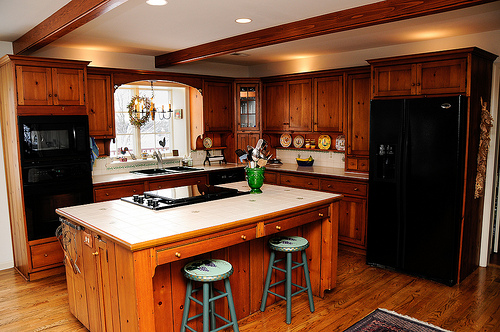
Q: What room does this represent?
A: It represents the kitchen.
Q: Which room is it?
A: It is a kitchen.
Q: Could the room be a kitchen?
A: Yes, it is a kitchen.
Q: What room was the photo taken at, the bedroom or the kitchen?
A: It was taken at the kitchen.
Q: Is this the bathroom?
A: No, it is the kitchen.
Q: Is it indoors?
A: Yes, it is indoors.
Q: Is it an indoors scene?
A: Yes, it is indoors.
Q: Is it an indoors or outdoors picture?
A: It is indoors.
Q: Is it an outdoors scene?
A: No, it is indoors.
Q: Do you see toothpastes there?
A: No, there are no toothpastes.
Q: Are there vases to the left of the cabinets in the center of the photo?
A: Yes, there is a vase to the left of the cabinets.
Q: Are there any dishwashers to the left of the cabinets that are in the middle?
A: No, there is a vase to the left of the cabinets.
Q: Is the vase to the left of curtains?
A: No, the vase is to the left of the cabinets.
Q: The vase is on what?
A: The vase is on the counter.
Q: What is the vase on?
A: The vase is on the counter.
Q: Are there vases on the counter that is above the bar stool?
A: Yes, there is a vase on the counter.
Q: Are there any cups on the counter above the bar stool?
A: No, there is a vase on the counter.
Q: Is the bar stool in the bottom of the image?
A: Yes, the bar stool is in the bottom of the image.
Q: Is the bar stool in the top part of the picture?
A: No, the bar stool is in the bottom of the image.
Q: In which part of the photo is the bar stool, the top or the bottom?
A: The bar stool is in the bottom of the image.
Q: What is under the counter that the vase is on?
A: The bar stool is under the counter.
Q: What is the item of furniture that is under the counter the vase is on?
A: The piece of furniture is a bar stool.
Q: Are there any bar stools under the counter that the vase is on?
A: Yes, there is a bar stool under the counter.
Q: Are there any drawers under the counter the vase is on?
A: No, there is a bar stool under the counter.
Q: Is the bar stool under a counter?
A: Yes, the bar stool is under a counter.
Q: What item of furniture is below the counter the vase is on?
A: The piece of furniture is a bar stool.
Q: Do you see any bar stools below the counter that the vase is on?
A: Yes, there is a bar stool below the counter.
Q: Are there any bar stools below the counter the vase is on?
A: Yes, there is a bar stool below the counter.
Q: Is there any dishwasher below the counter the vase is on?
A: No, there is a bar stool below the counter.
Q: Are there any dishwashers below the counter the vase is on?
A: No, there is a bar stool below the counter.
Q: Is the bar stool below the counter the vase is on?
A: Yes, the bar stool is below the counter.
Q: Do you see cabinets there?
A: Yes, there is a cabinet.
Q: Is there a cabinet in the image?
A: Yes, there is a cabinet.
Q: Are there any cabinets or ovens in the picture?
A: Yes, there is a cabinet.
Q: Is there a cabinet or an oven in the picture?
A: Yes, there is a cabinet.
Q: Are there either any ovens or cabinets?
A: Yes, there is a cabinet.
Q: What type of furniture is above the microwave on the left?
A: The piece of furniture is a cabinet.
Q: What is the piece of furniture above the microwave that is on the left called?
A: The piece of furniture is a cabinet.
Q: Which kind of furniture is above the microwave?
A: The piece of furniture is a cabinet.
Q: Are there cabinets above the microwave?
A: Yes, there is a cabinet above the microwave.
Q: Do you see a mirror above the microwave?
A: No, there is a cabinet above the microwave.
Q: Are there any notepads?
A: No, there are no notepads.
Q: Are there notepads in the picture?
A: No, there are no notepads.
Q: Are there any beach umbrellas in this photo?
A: No, there are no beach umbrellas.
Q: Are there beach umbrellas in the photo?
A: No, there are no beach umbrellas.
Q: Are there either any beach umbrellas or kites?
A: No, there are no beach umbrellas or kites.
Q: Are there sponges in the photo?
A: No, there are no sponges.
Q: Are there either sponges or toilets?
A: No, there are no sponges or toilets.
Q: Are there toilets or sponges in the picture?
A: No, there are no sponges or toilets.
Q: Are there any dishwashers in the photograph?
A: No, there are no dishwashers.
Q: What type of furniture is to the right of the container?
A: The pieces of furniture are cabinets.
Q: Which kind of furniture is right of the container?
A: The pieces of furniture are cabinets.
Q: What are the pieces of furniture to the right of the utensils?
A: The pieces of furniture are cabinets.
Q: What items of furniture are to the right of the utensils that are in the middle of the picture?
A: The pieces of furniture are cabinets.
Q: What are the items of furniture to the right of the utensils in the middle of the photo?
A: The pieces of furniture are cabinets.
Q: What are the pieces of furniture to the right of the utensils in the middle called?
A: The pieces of furniture are cabinets.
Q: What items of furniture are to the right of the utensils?
A: The pieces of furniture are cabinets.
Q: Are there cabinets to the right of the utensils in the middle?
A: Yes, there are cabinets to the right of the utensils.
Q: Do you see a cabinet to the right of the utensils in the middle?
A: Yes, there are cabinets to the right of the utensils.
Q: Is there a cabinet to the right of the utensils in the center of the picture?
A: Yes, there are cabinets to the right of the utensils.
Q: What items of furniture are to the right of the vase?
A: The pieces of furniture are cabinets.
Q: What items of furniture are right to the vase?
A: The pieces of furniture are cabinets.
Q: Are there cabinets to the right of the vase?
A: Yes, there are cabinets to the right of the vase.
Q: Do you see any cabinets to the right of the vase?
A: Yes, there are cabinets to the right of the vase.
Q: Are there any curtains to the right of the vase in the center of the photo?
A: No, there are cabinets to the right of the vase.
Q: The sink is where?
A: The sink is in the kitchen.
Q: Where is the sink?
A: The sink is in the kitchen.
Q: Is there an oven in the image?
A: Yes, there is an oven.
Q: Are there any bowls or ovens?
A: Yes, there is an oven.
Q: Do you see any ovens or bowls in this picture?
A: Yes, there is an oven.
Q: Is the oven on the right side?
A: No, the oven is on the left of the image.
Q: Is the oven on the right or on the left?
A: The oven is on the left of the image.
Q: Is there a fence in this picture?
A: No, there are no fences.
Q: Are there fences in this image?
A: No, there are no fences.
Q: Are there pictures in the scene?
A: No, there are no pictures.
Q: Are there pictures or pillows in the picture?
A: No, there are no pictures or pillows.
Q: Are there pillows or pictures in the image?
A: No, there are no pictures or pillows.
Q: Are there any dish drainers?
A: No, there are no dish drainers.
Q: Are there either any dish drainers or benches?
A: No, there are no dish drainers or benches.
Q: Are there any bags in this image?
A: No, there are no bags.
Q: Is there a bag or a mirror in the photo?
A: No, there are no bags or mirrors.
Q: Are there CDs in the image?
A: No, there are no cds.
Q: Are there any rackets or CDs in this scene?
A: No, there are no CDs or rackets.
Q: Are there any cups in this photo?
A: No, there are no cups.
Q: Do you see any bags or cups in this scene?
A: No, there are no cups or bags.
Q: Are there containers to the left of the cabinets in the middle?
A: Yes, there is a container to the left of the cabinets.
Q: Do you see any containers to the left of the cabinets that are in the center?
A: Yes, there is a container to the left of the cabinets.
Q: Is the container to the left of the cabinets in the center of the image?
A: Yes, the container is to the left of the cabinets.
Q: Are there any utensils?
A: Yes, there are utensils.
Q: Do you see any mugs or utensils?
A: Yes, there are utensils.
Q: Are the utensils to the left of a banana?
A: Yes, the utensils are to the left of a banana.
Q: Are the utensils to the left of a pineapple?
A: No, the utensils are to the left of a banana.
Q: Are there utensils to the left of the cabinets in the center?
A: Yes, there are utensils to the left of the cabinets.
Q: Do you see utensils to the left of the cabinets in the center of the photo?
A: Yes, there are utensils to the left of the cabinets.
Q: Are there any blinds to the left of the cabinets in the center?
A: No, there are utensils to the left of the cabinets.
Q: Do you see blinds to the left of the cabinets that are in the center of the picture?
A: No, there are utensils to the left of the cabinets.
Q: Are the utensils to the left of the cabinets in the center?
A: Yes, the utensils are to the left of the cabinets.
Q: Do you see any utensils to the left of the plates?
A: Yes, there are utensils to the left of the plates.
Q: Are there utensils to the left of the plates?
A: Yes, there are utensils to the left of the plates.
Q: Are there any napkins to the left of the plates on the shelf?
A: No, there are utensils to the left of the plates.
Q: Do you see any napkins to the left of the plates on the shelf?
A: No, there are utensils to the left of the plates.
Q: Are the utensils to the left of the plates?
A: Yes, the utensils are to the left of the plates.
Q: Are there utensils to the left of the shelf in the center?
A: Yes, there are utensils to the left of the shelf.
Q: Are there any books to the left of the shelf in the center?
A: No, there are utensils to the left of the shelf.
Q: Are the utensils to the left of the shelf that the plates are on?
A: Yes, the utensils are to the left of the shelf.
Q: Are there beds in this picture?
A: No, there are no beds.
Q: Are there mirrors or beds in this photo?
A: No, there are no beds or mirrors.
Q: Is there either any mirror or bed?
A: No, there are no beds or mirrors.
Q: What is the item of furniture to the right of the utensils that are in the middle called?
A: The piece of furniture is a shelf.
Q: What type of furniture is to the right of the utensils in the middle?
A: The piece of furniture is a shelf.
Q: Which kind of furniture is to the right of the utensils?
A: The piece of furniture is a shelf.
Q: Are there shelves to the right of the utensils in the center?
A: Yes, there is a shelf to the right of the utensils.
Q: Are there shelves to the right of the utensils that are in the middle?
A: Yes, there is a shelf to the right of the utensils.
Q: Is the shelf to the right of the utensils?
A: Yes, the shelf is to the right of the utensils.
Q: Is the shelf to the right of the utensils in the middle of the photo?
A: Yes, the shelf is to the right of the utensils.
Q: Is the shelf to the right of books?
A: No, the shelf is to the right of the utensils.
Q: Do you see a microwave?
A: Yes, there is a microwave.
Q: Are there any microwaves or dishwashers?
A: Yes, there is a microwave.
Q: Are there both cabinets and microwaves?
A: Yes, there are both a microwave and cabinets.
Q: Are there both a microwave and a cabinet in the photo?
A: Yes, there are both a microwave and a cabinet.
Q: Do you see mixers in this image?
A: No, there are no mixers.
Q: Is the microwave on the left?
A: Yes, the microwave is on the left of the image.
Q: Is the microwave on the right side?
A: No, the microwave is on the left of the image.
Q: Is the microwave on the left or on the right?
A: The microwave is on the left of the image.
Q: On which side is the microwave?
A: The microwave is on the left of the image.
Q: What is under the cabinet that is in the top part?
A: The microwave is under the cabinet.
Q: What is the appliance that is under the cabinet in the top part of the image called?
A: The appliance is a microwave.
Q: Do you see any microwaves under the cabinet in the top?
A: Yes, there is a microwave under the cabinet.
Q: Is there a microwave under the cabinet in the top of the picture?
A: Yes, there is a microwave under the cabinet.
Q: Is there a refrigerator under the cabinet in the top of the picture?
A: No, there is a microwave under the cabinet.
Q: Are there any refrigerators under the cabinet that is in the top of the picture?
A: No, there is a microwave under the cabinet.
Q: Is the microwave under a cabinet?
A: Yes, the microwave is under a cabinet.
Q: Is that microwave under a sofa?
A: No, the microwave is under a cabinet.